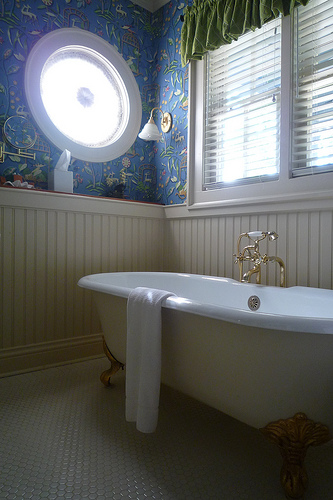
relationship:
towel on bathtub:
[119, 289, 170, 445] [83, 266, 330, 428]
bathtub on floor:
[83, 266, 330, 428] [5, 412, 116, 492]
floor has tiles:
[5, 412, 116, 492] [44, 430, 64, 442]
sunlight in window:
[60, 61, 116, 132] [38, 30, 145, 165]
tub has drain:
[83, 266, 330, 428] [239, 295, 264, 313]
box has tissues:
[52, 165, 81, 193] [52, 149, 83, 196]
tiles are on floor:
[44, 430, 64, 442] [5, 412, 116, 492]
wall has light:
[153, 48, 178, 91] [135, 108, 174, 153]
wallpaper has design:
[124, 24, 190, 72] [127, 41, 152, 66]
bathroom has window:
[8, 6, 330, 494] [38, 30, 145, 165]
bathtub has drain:
[83, 266, 330, 428] [239, 295, 264, 313]